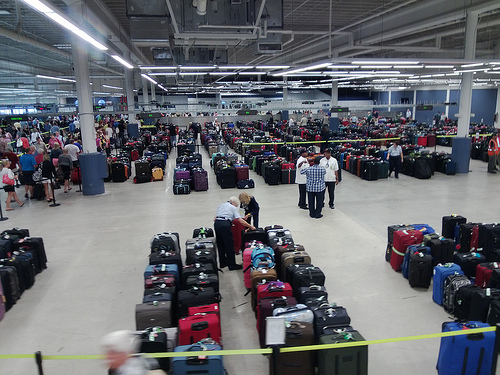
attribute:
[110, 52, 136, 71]
light — overhead, fluorescent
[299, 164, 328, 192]
shirt — blue, white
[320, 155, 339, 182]
top — white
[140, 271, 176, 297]
suitcase — pink, burgundy, beige, purple, white, roundish, grouped, lined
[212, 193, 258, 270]
person — bending, talking, large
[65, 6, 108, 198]
post — concrete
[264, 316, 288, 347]
sign — white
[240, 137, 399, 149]
strap — yellow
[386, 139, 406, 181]
woman — walking, searching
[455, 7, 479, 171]
pole — concrete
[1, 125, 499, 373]
floor — concrete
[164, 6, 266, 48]
pipe — running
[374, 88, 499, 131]
wall — blue